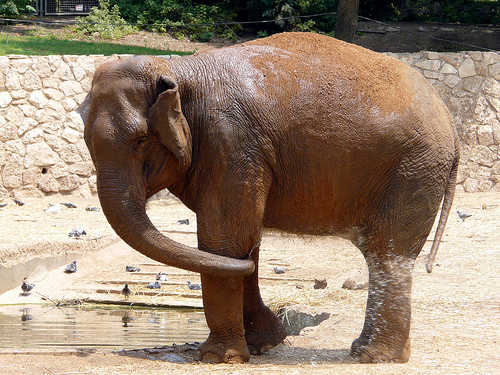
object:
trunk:
[96, 169, 256, 277]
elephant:
[75, 31, 460, 364]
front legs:
[197, 151, 273, 333]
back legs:
[351, 224, 432, 341]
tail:
[423, 105, 461, 274]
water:
[2, 299, 212, 349]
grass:
[1, 28, 200, 56]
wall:
[1, 49, 499, 207]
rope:
[2, 10, 499, 50]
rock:
[21, 75, 73, 179]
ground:
[1, 184, 499, 374]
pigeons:
[15, 196, 203, 329]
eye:
[134, 135, 149, 151]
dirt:
[238, 30, 409, 113]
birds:
[0, 194, 203, 329]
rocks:
[313, 276, 369, 290]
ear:
[148, 77, 191, 159]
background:
[2, 0, 499, 59]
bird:
[65, 260, 77, 273]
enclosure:
[5, 52, 499, 374]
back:
[176, 31, 452, 123]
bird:
[122, 283, 132, 300]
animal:
[75, 31, 462, 364]